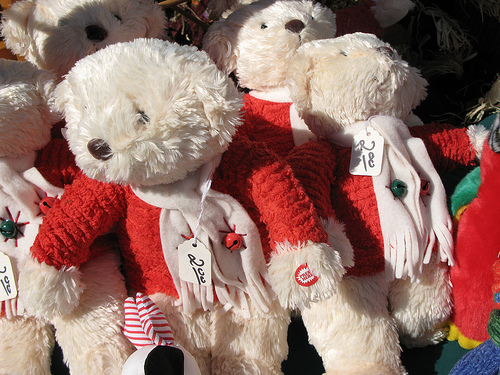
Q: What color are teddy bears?
A: Beige.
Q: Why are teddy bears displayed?
A: To be sold.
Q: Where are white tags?
A: On the teddy bears.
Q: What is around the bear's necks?
A: Scarves.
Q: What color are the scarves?
A: White.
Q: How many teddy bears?
A: Five.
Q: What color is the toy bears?
A: White.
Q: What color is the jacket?
A: Red.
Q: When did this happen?
A: During the day time.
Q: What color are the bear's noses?
A: Black.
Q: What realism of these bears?
A: Fake.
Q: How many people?
A: None.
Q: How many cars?
A: None.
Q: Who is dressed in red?
A: A teddy bear.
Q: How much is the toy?
A: Two dollars.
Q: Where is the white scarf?
A: On a bear.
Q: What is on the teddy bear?
A: A white scarf.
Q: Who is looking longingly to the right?
A: A bear.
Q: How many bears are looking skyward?
A: Two.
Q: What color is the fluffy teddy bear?
A: White.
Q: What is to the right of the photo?
A: A white fluffy teddy bear.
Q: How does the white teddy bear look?
A: Fluffy.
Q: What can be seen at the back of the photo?
A: A white fluffy teddy bear.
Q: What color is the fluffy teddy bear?
A: White.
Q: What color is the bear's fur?
A: White.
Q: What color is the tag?
A: White.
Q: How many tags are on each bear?
A: 1.